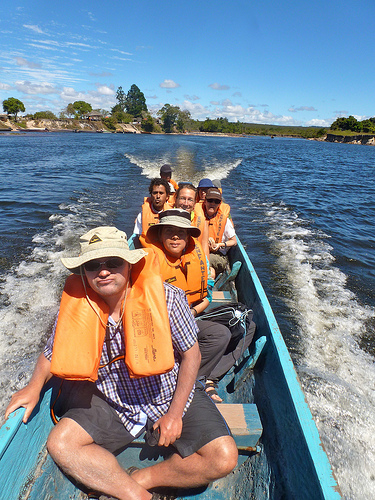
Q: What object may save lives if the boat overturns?
A: Life jacket.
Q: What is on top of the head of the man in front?
A: Hat.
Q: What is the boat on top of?
A: Water.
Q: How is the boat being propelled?
A: Motor.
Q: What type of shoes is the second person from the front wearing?
A: Sandals.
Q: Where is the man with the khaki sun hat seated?
A: Front.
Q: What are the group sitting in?
A: Boat.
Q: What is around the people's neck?
A: Lifejacket.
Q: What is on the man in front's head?
A: Hat.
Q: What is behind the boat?
A: Water wake.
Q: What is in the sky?
A: Clouds.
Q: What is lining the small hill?
A: Trees.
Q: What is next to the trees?
A: Gazebo.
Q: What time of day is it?
A: Afternoon.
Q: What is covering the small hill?
A: Grass.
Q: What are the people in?
A: Boat.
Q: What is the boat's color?
A: Blue.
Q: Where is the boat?
A: Water.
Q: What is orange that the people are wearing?
A: Life jacket.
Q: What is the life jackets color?
A: Orange.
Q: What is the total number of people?
A: 7.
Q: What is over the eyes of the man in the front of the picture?
A: Sunglasses.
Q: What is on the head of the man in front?
A: Hat.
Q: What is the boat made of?
A: Wood.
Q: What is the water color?
A: Blue.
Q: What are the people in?
A: A boat.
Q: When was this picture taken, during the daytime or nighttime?
A: Daytime.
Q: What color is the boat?
A: Blue.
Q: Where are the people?
A: The boat.